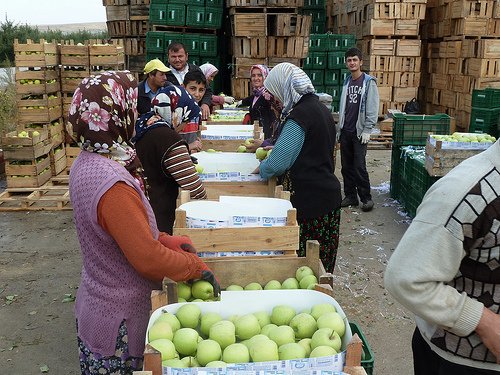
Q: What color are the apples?
A: Green.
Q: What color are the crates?
A: Brown.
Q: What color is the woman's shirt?
A: Purple.